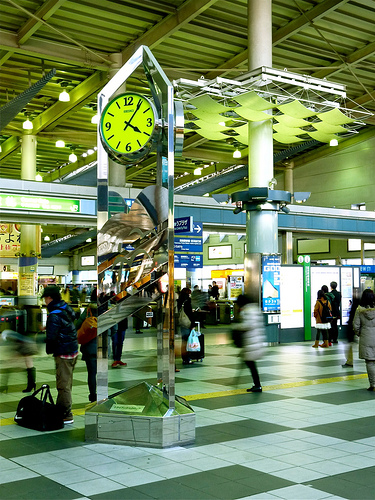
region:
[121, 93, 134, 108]
black number on clock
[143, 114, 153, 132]
black number on clock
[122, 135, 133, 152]
black number on clock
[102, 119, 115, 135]
black number on clock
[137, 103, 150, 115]
black line on clock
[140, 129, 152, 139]
black line on clock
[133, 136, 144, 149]
black line on clock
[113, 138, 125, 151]
black line on clock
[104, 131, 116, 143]
black line on clock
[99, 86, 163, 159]
bright yellow clock face in station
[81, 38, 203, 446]
shiny silver sculpture with yellow clock face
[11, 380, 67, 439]
black duffle bag sitting on floor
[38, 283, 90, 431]
man wearing khaki's standing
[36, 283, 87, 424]
man wearing black hat and blue and black jacket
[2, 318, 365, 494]
grey and green colorblocked and tiled floor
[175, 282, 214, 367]
woman with luggage cart and holding plastic bag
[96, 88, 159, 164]
time reads 4:05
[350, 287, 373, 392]
woman with dark hair and khaki down jacket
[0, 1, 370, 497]
interior of modernized transportation station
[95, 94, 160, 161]
clock face indication 4:05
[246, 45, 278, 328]
large white interior building column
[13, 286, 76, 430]
man in blue and black jacket and tan pants with duffel bag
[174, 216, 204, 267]
blue and white directional signs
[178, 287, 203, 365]
woman with black hair and wheeled suitcase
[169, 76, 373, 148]
sculpture suspended from column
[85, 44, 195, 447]
open aluminum and granite clock tower with three clock faces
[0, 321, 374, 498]
green-gray and white stone tiled floor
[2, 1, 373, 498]
busy metropolitan transportation station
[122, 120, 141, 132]
the hour hand of a clock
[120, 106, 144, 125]
the minute hand of a clock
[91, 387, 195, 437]
the base of a glass stand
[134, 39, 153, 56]
the tip of a glass stand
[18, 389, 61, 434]
a black bag on the floor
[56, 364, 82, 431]
the legs of a person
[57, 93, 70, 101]
a lit bulb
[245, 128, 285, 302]
the pillar of a building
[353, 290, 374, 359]
a person walking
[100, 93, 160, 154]
a clock on a glass stand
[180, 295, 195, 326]
a bag strapped on the shoulder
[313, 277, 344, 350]
3 people standing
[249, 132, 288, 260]
the pillar of a the building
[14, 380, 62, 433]
a black bag on the ground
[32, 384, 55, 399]
the holding straps of a bag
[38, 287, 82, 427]
a person standing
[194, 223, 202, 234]
a white arrow pointing to the right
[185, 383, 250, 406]
a yellow stripe on the floor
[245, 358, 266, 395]
a leg of a person